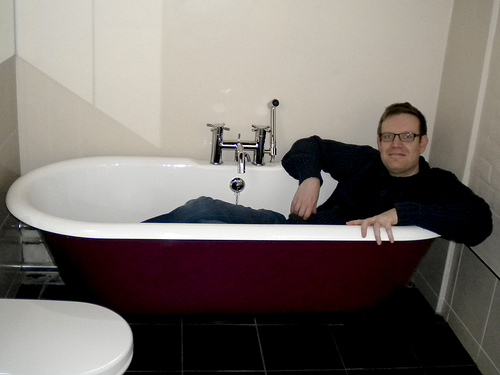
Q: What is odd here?
A: Man in tub.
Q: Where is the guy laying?
A: Bathtub.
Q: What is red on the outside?
A: Bathtub.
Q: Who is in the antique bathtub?
A: Man in black.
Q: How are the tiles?
A: Black squares.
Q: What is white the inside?
A: Bathtub.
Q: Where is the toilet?
A: Across from tub.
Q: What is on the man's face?
A: Glasses.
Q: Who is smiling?
A: Man in black.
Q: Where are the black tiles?
A: On floor.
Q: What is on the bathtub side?
A: Man's hand.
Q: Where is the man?
A: In the bathtub.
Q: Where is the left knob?
A: On the tub.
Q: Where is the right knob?
A: On the tub.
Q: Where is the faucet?
A: On the tub.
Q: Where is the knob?
A: On the tub.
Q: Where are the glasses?
A: On the man.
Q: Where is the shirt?
A: On the man.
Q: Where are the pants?
A: On the man.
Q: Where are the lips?
A: On the man.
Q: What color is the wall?
A: White.